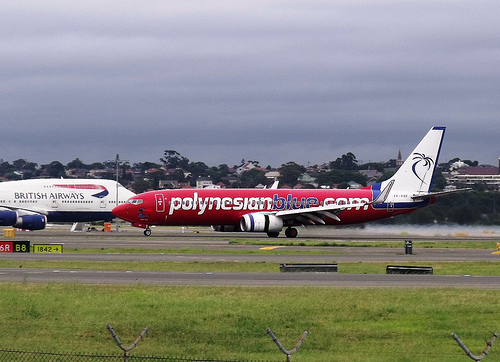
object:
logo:
[168, 191, 367, 214]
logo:
[13, 191, 83, 198]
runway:
[0, 265, 497, 292]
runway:
[1, 250, 498, 260]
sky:
[0, 0, 499, 168]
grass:
[0, 225, 499, 360]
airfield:
[1, 165, 500, 361]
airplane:
[110, 126, 472, 239]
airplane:
[0, 179, 138, 230]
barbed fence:
[0, 347, 250, 359]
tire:
[285, 228, 298, 238]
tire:
[267, 230, 279, 237]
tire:
[143, 229, 151, 237]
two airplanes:
[0, 125, 445, 239]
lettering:
[14, 189, 86, 199]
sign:
[33, 241, 63, 252]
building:
[449, 163, 499, 190]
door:
[155, 193, 165, 213]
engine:
[240, 211, 283, 233]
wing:
[277, 180, 396, 217]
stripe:
[370, 182, 425, 211]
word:
[269, 192, 319, 212]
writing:
[166, 191, 273, 216]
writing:
[323, 193, 368, 213]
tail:
[385, 125, 447, 200]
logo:
[410, 152, 436, 186]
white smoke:
[281, 216, 499, 240]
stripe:
[248, 213, 255, 233]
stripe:
[261, 213, 270, 233]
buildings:
[0, 155, 406, 192]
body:
[110, 187, 387, 225]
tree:
[42, 160, 64, 177]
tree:
[86, 161, 106, 170]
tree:
[132, 161, 159, 170]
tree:
[187, 161, 207, 179]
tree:
[212, 160, 230, 176]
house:
[235, 159, 259, 174]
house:
[86, 165, 106, 178]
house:
[359, 169, 385, 180]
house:
[194, 175, 224, 189]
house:
[265, 169, 282, 179]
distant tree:
[318, 169, 368, 186]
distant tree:
[446, 200, 474, 222]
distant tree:
[237, 167, 267, 182]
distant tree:
[277, 160, 306, 186]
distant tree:
[158, 149, 190, 169]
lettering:
[273, 194, 285, 210]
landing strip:
[1, 204, 500, 289]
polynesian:
[167, 189, 272, 216]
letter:
[168, 195, 181, 215]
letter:
[180, 197, 192, 209]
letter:
[195, 195, 208, 215]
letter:
[207, 195, 221, 210]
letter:
[221, 195, 233, 210]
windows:
[129, 198, 144, 204]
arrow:
[54, 247, 59, 251]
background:
[0, 150, 498, 230]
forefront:
[0, 280, 499, 361]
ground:
[0, 217, 499, 362]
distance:
[0, 145, 498, 230]